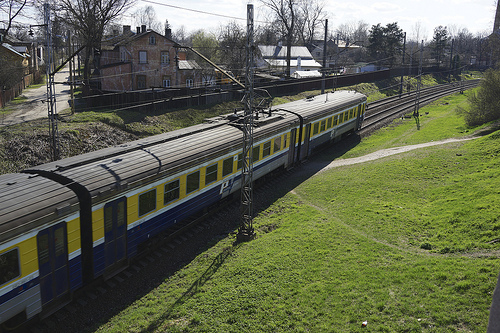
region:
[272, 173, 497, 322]
a patch of short green grass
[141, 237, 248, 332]
the shadow of a metal phone pole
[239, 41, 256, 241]
a metal phone line pole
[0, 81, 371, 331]
a blue, white, and yellow train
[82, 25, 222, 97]
a pretty house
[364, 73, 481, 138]
a pair of train tracks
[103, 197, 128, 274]
blue double train doors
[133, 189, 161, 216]
a train window that is closed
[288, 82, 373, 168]
the back train car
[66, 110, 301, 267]
yellow and blue train with white accents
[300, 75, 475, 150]
train on tracks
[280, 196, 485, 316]
green grassy meadow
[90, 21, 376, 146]
houses near train tracks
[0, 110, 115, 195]
hill by train tracks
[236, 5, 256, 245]
metal tower by train track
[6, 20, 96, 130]
road running by houses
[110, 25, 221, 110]
pink house near tracks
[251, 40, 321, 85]
white barn near tracks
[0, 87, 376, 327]
passenger train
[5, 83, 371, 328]
a train on a railroad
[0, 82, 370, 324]
roof of train is black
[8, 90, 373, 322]
side of train is yellow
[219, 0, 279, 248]
a pole on the grass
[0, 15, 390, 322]
train pass in front a small city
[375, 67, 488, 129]
railroad in front a city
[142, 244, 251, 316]
shadow cast on the ground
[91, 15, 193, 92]
a house of brick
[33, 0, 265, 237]
two poles on side a train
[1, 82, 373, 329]
train is in motion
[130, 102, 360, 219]
Windows on side of train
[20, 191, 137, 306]
Doors on side of train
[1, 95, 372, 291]
Yellow stripe on side of train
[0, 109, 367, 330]
Blue stripe on side of train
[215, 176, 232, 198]
Letter "P" on side of train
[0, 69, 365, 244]
Gray roof on top of train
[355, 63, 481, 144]
Sets of train tracks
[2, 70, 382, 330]
Yellow, white, blue and gray train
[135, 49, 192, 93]
Windows on side of house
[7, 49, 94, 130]
Gray road in between houses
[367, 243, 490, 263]
Foot trail cutting through grass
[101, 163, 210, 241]
Yellow, white, and blue train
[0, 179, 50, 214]
Black ridges on top of train cars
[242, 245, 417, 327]
Short green grass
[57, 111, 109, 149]
Rocky slope with patchy grass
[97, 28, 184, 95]
Old building in background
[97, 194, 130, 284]
Side door of passenger train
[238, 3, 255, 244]
Tall pole next to train track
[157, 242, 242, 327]
Deep shadows on grass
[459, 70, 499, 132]
Tall shrub in background